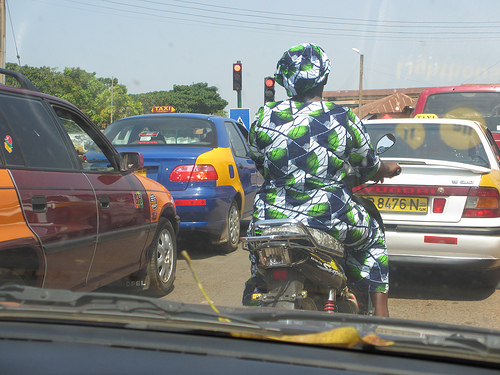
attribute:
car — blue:
[63, 93, 299, 271]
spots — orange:
[178, 126, 254, 205]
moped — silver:
[234, 123, 428, 321]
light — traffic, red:
[256, 63, 296, 112]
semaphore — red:
[260, 62, 282, 105]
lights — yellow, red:
[216, 56, 312, 110]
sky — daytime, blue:
[0, 3, 495, 110]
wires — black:
[85, 2, 497, 49]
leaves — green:
[51, 69, 234, 129]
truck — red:
[407, 76, 494, 141]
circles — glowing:
[263, 72, 275, 87]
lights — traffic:
[252, 68, 286, 115]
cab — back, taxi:
[297, 113, 492, 301]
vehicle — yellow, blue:
[76, 100, 286, 274]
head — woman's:
[269, 34, 343, 111]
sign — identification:
[123, 90, 189, 130]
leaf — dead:
[208, 298, 396, 368]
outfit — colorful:
[198, 47, 415, 259]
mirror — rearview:
[361, 129, 402, 171]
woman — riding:
[225, 32, 389, 239]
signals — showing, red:
[211, 50, 298, 125]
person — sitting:
[239, 49, 459, 229]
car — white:
[358, 123, 487, 273]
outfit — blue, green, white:
[215, 39, 364, 238]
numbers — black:
[358, 190, 428, 220]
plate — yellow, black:
[346, 189, 444, 242]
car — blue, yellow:
[136, 109, 271, 267]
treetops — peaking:
[44, 46, 230, 136]